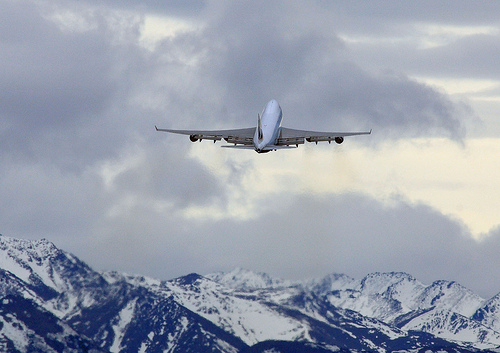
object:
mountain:
[0, 237, 498, 349]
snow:
[0, 235, 499, 351]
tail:
[254, 113, 265, 146]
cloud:
[0, 5, 498, 283]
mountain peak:
[179, 271, 205, 285]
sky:
[2, 3, 499, 275]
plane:
[152, 100, 373, 158]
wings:
[150, 125, 372, 144]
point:
[232, 261, 248, 272]